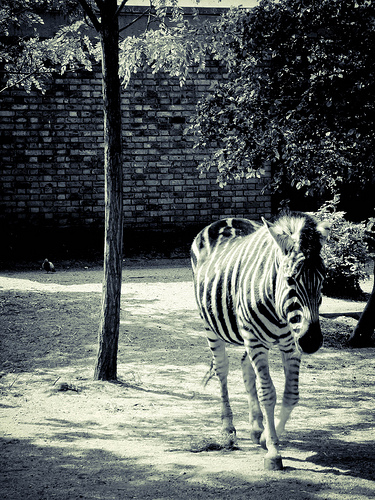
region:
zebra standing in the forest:
[189, 210, 334, 482]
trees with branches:
[224, 6, 372, 201]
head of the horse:
[270, 223, 328, 359]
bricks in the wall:
[137, 100, 246, 207]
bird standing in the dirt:
[37, 256, 59, 275]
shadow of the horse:
[305, 426, 370, 483]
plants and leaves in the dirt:
[315, 200, 363, 310]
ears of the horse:
[261, 210, 328, 261]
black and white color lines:
[197, 256, 258, 331]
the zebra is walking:
[191, 213, 345, 450]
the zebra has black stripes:
[217, 232, 274, 305]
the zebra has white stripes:
[246, 236, 277, 286]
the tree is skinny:
[66, 82, 147, 463]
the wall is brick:
[142, 99, 196, 164]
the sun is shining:
[149, 299, 174, 405]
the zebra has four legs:
[160, 338, 312, 487]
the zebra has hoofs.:
[245, 452, 310, 481]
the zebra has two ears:
[224, 205, 345, 266]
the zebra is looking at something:
[249, 241, 371, 364]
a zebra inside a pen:
[170, 199, 335, 470]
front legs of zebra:
[248, 345, 297, 474]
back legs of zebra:
[205, 339, 259, 449]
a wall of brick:
[2, 37, 204, 263]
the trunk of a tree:
[88, 5, 133, 384]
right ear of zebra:
[311, 212, 342, 254]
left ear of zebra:
[261, 212, 299, 259]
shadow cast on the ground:
[292, 411, 371, 494]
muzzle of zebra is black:
[291, 316, 327, 363]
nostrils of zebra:
[295, 333, 325, 354]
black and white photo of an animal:
[15, 17, 357, 489]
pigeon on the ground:
[33, 250, 56, 270]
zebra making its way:
[186, 210, 327, 469]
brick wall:
[5, 105, 95, 215]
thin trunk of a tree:
[90, 203, 124, 378]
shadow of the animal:
[286, 425, 368, 478]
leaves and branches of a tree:
[0, 0, 210, 90]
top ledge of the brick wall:
[127, 0, 224, 12]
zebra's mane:
[270, 205, 321, 243]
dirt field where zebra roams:
[16, 271, 372, 496]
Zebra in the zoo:
[175, 183, 352, 483]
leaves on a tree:
[129, 8, 320, 108]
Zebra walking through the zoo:
[269, 242, 315, 441]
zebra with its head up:
[261, 224, 345, 367]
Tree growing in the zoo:
[63, 185, 151, 394]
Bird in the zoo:
[36, 252, 62, 277]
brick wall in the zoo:
[42, 85, 218, 207]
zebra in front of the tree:
[184, 211, 330, 454]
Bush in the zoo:
[295, 188, 366, 313]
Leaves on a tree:
[121, 5, 226, 86]